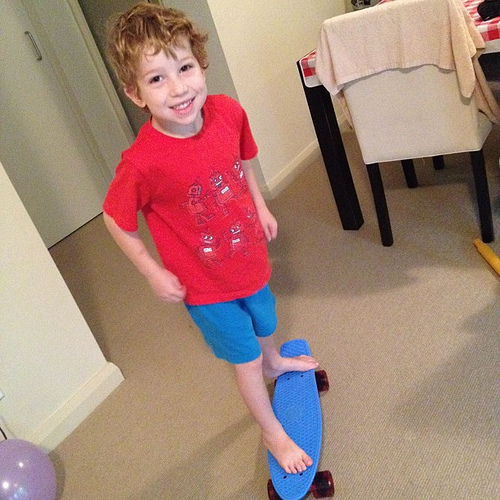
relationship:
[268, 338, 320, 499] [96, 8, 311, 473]
skateboard below boy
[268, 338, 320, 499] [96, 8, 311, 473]
skateboard under boy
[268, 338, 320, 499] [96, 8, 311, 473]
skateboard close to boy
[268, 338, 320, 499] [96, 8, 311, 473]
skateboard next to boy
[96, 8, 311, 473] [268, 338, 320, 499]
boy above skateboard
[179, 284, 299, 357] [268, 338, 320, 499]
shorts above skateboard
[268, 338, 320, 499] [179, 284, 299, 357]
skateboard below shorts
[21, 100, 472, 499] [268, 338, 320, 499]
floor below skateboard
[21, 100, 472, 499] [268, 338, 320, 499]
floor under skateboard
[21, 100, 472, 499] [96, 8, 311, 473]
floor under boy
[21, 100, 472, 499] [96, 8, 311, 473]
floor below boy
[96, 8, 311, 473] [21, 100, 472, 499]
boy above floor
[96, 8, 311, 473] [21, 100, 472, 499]
boy on floor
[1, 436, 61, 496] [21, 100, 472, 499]
ball on floor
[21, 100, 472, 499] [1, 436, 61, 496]
floor under ball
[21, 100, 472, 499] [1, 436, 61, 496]
floor below ball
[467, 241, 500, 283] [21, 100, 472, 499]
toy on floor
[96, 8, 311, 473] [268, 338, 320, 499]
boy on skateboard